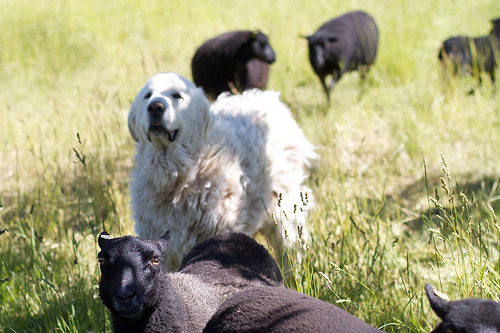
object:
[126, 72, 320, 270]
dog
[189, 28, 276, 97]
sheep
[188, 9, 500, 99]
three sheep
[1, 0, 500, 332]
grass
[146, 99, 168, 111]
nose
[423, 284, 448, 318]
ear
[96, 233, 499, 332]
sheep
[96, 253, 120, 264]
eyes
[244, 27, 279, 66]
head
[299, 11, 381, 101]
sheep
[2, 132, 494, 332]
taller blades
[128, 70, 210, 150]
head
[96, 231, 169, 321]
head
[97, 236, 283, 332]
sheep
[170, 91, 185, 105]
eye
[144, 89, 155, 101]
eye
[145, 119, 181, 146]
mouth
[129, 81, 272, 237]
shadow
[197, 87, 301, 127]
back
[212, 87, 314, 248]
sunlight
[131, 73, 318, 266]
hair